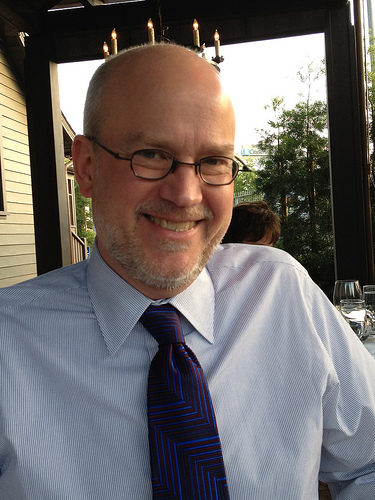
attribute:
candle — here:
[148, 14, 160, 43]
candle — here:
[110, 24, 122, 51]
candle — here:
[189, 20, 207, 49]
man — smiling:
[11, 39, 371, 500]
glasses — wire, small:
[90, 138, 249, 196]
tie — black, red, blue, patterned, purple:
[138, 308, 232, 500]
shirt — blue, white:
[4, 248, 371, 499]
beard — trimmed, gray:
[84, 175, 238, 287]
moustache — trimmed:
[138, 205, 208, 223]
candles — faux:
[101, 22, 226, 58]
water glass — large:
[324, 275, 360, 320]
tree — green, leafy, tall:
[260, 98, 331, 296]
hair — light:
[80, 60, 122, 141]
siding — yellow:
[0, 65, 41, 281]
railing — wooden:
[66, 230, 95, 266]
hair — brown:
[232, 198, 280, 236]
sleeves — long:
[327, 342, 374, 500]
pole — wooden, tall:
[325, 27, 374, 292]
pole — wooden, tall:
[28, 62, 71, 272]